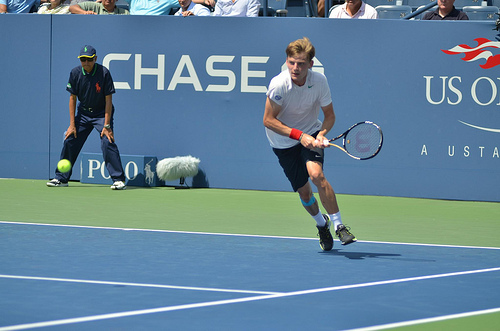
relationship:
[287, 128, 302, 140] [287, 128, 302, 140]
sweatband over sweatband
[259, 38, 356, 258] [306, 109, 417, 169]
player holding racket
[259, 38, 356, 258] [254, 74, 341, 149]
player wearing white outfit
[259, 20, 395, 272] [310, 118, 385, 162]
player holding tennis racket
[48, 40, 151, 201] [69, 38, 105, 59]
linesman in cap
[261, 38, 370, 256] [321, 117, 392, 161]
man holding tennis racket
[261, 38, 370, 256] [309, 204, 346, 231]
man wearing white socks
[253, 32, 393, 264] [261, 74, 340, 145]
man wearing white outfit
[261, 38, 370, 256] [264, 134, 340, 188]
man wearing black shorts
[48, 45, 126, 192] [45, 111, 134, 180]
linesman wearing blue pants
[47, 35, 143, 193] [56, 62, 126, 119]
umpire wearing blue shirt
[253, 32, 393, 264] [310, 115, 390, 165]
man holding tennis racket